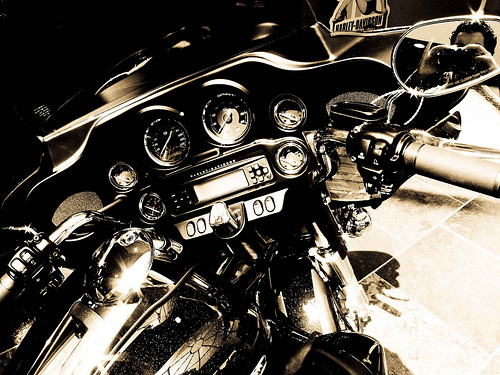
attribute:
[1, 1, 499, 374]
photograph is black — white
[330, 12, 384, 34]
company logo — motorcycle , top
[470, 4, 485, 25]
sparkle of light — reflected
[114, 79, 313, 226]
control panel — rectangular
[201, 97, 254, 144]
circle — silver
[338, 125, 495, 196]
handlebar — motorcycle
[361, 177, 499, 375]
ceramic floor — white, tiled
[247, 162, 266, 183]
buttons — bike handle.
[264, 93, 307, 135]
black gauge — chrome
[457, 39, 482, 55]
finger — extended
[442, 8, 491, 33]
hair — very dark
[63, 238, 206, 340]
attachment — round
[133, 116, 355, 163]
speed dials — round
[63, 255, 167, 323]
gas cap — silver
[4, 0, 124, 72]
background — black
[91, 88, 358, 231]
dials — round, electronic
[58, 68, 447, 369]
bike — parked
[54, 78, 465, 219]
handle. — bike .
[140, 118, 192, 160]
speedometer — black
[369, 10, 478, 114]
mirror — shiny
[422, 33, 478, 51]
reflection — photographer 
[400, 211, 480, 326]
concrete — overexposed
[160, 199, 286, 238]
buttons — chrome